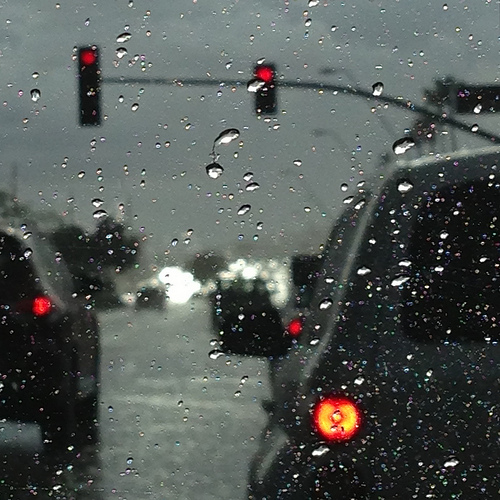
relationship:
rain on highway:
[180, 117, 259, 188] [77, 269, 277, 461]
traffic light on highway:
[249, 58, 282, 121] [0, 269, 297, 500]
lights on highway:
[79, 49, 98, 64] [0, 269, 297, 500]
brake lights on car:
[314, 393, 363, 445] [259, 167, 491, 500]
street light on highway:
[249, 58, 282, 121] [0, 269, 297, 500]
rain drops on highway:
[205, 162, 226, 180] [0, 269, 297, 500]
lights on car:
[30, 294, 55, 318] [259, 167, 491, 500]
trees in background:
[412, 78, 468, 146] [176, 0, 499, 423]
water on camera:
[180, 117, 259, 188] [176, 0, 499, 423]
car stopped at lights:
[259, 167, 491, 500] [71, 40, 288, 127]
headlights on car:
[287, 320, 302, 336] [2, 223, 101, 461]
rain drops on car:
[203, 126, 245, 183] [259, 167, 491, 500]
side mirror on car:
[221, 309, 286, 358] [259, 167, 491, 500]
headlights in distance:
[289, 315, 301, 338] [131, 279, 171, 315]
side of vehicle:
[20, 234, 108, 433] [2, 223, 101, 461]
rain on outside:
[180, 117, 259, 188] [176, 0, 499, 423]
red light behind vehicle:
[249, 58, 282, 121] [207, 275, 280, 338]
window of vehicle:
[407, 194, 499, 328] [259, 167, 491, 500]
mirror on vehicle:
[221, 309, 286, 358] [259, 167, 491, 500]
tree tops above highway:
[406, 71, 465, 115] [0, 269, 297, 500]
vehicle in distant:
[131, 279, 171, 315] [105, 221, 213, 351]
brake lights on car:
[278, 308, 360, 450] [259, 167, 491, 500]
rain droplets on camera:
[203, 126, 245, 183] [6, 3, 498, 483]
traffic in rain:
[4, 218, 499, 456] [180, 117, 259, 188]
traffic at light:
[4, 218, 499, 456] [71, 40, 288, 127]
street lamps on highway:
[71, 40, 288, 127] [0, 269, 297, 500]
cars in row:
[4, 218, 499, 456] [211, 253, 413, 500]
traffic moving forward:
[4, 218, 499, 456] [120, 275, 180, 336]